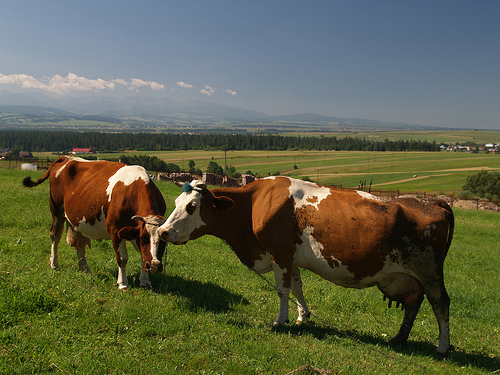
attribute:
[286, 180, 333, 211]
spots — white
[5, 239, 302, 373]
grass — green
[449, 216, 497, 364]
grass — green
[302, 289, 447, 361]
grass — green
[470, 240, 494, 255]
grass — green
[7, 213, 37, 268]
grass — green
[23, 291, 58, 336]
grass — green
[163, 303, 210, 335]
grass — green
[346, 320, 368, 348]
grass — green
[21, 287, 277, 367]
grass — green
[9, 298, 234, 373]
grass — green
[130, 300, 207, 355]
grass — green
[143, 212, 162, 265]
streak — white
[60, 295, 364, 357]
grass — green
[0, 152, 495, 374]
grass — green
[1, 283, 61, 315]
grass — green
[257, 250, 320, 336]
legs — white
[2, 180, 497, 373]
grass — green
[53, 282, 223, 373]
grass — green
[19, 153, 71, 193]
tail — long